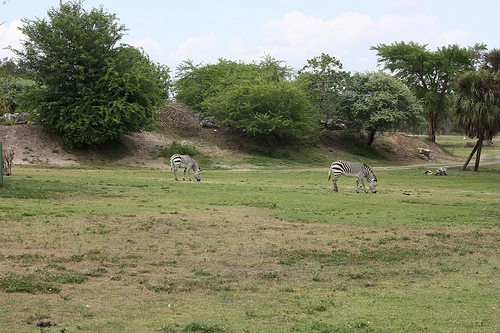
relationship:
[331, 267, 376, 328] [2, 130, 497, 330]
grass in field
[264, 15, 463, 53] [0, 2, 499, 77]
clouds in sky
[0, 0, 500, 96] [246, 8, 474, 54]
sky with clouds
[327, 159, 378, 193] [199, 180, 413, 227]
zebra on grass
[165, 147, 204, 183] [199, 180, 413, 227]
zebra grazing on grass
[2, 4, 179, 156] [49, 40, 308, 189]
bush on side of hill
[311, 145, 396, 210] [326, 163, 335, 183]
zebra with tail